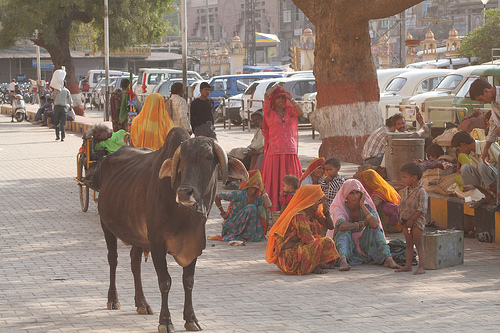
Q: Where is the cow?
A: On the sidewalk.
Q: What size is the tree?
A: Large.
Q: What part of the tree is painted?
A: The trunk.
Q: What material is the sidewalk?
A: Red brick.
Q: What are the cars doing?
A: Parked.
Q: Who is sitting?
A: Women and children.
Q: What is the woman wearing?
A: Red outfit.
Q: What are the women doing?
A: Sitting.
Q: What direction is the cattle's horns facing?
A: Downward.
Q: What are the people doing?
A: Sitting.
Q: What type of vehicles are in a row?
A: Cars.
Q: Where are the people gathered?
A: In a city.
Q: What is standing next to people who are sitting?
A: A cow.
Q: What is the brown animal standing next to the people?
A: A cow.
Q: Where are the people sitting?
A: On the sidewalk.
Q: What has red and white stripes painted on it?
A: A tree.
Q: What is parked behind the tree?
A: Cars.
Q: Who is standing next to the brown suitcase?
A: Little boy.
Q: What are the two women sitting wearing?
A: Saris.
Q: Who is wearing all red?
A: The woman.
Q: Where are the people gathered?
A: Under the tree.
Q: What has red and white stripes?
A: The brown tree.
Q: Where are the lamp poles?
A: On the street.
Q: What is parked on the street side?
A: Cars.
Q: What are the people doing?
A: Walking.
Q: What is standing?
A: The animal.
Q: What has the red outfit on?
A: The woman.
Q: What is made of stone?
A: The ground.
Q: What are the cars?
A: Parked.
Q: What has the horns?
A: The animal.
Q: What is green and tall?
A: The tree.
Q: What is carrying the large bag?
A: The man.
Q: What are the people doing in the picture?
A: The people are sitting on the ground.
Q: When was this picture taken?
A: During the day.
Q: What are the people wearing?
A: Colorful clothing.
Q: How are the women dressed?
A: The women have head scarves around their heads.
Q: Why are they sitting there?
A: They are waiting for something.